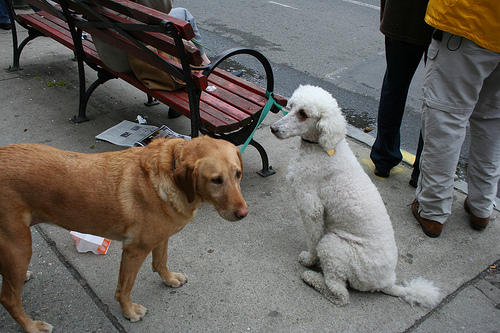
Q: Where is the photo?
A: Street.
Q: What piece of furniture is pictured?
A: Bench.